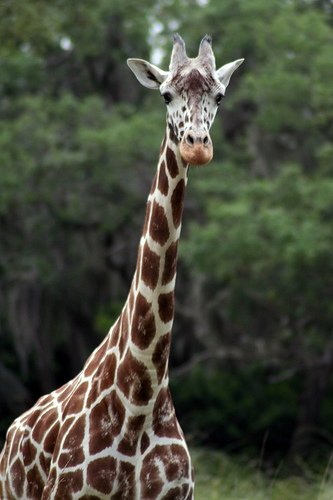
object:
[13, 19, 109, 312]
trees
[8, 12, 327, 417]
background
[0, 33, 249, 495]
giraffe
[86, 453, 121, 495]
spots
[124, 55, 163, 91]
ear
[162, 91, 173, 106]
eye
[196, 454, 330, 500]
grass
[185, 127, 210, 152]
nose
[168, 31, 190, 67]
ossicones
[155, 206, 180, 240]
fur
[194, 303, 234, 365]
bark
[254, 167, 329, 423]
tree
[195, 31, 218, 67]
horns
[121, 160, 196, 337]
neck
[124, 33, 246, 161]
head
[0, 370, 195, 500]
body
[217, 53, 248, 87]
ear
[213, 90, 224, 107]
eye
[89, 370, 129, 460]
print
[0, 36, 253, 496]
animal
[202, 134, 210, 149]
nostril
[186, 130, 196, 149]
nostril